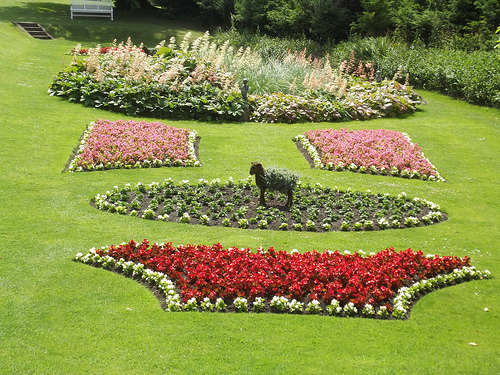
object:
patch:
[89, 174, 449, 234]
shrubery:
[338, 16, 496, 101]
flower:
[291, 297, 301, 315]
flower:
[303, 296, 323, 315]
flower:
[105, 243, 465, 314]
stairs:
[11, 14, 59, 44]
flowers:
[42, 23, 427, 144]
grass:
[43, 89, 410, 354]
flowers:
[116, 110, 491, 320]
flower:
[303, 283, 316, 296]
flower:
[371, 280, 387, 295]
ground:
[6, 3, 498, 373]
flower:
[339, 149, 353, 161]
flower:
[352, 132, 359, 137]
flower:
[377, 145, 393, 160]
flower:
[395, 160, 407, 170]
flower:
[414, 163, 434, 171]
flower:
[185, 287, 204, 297]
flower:
[303, 282, 325, 296]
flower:
[388, 268, 400, 282]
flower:
[403, 241, 416, 262]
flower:
[217, 258, 239, 269]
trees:
[397, 6, 424, 54]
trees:
[449, 2, 488, 39]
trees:
[302, 2, 346, 52]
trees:
[264, 1, 301, 44]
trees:
[223, 0, 259, 42]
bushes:
[350, 35, 385, 77]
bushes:
[437, 62, 467, 106]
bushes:
[376, 52, 399, 89]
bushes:
[477, 72, 499, 97]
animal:
[246, 160, 302, 212]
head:
[247, 160, 267, 179]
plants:
[100, 23, 432, 114]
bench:
[63, 1, 119, 25]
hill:
[3, 1, 200, 55]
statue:
[239, 76, 252, 111]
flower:
[92, 248, 107, 257]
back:
[104, 151, 433, 352]